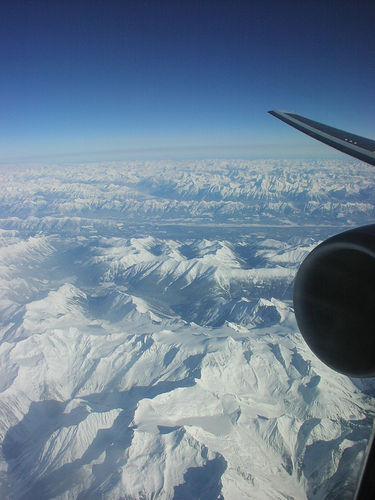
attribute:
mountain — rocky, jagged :
[39, 257, 292, 479]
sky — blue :
[3, 2, 374, 167]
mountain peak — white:
[129, 417, 227, 498]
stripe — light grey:
[269, 109, 374, 162]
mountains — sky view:
[49, 148, 372, 452]